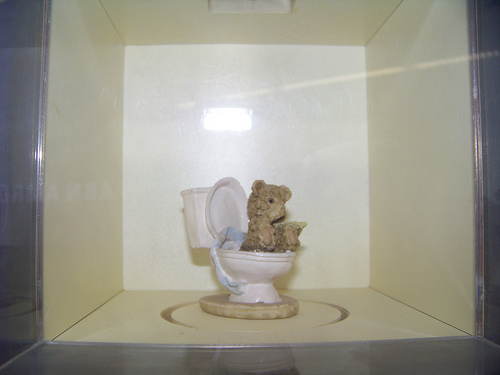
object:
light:
[203, 101, 255, 133]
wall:
[1, 2, 478, 367]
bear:
[240, 179, 308, 255]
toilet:
[169, 171, 301, 308]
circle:
[155, 289, 360, 333]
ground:
[59, 275, 469, 351]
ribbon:
[201, 221, 256, 296]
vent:
[202, 2, 297, 20]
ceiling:
[79, 2, 402, 45]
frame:
[14, 2, 488, 367]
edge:
[293, 219, 306, 229]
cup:
[287, 219, 309, 235]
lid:
[202, 172, 246, 237]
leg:
[244, 226, 278, 250]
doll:
[240, 177, 308, 254]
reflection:
[204, 103, 257, 131]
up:
[198, 174, 260, 240]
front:
[272, 249, 296, 302]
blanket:
[209, 219, 257, 294]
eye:
[267, 196, 278, 205]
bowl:
[222, 238, 296, 264]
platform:
[200, 292, 298, 319]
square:
[208, 0, 299, 25]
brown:
[256, 193, 277, 231]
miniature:
[177, 172, 299, 301]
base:
[197, 292, 300, 321]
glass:
[46, 4, 477, 352]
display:
[15, 0, 491, 364]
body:
[246, 216, 304, 260]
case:
[18, 1, 487, 374]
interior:
[124, 47, 385, 288]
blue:
[206, 224, 255, 292]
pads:
[256, 226, 304, 249]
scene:
[39, 5, 481, 354]